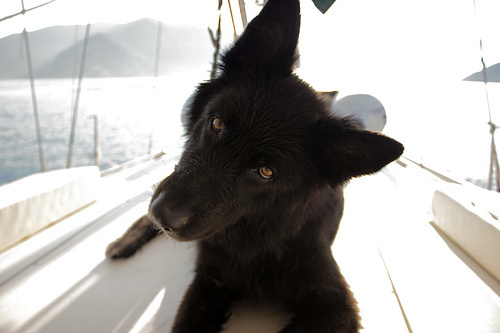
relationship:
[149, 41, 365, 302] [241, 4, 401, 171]
dog black ears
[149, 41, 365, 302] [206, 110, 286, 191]
dog orange eyes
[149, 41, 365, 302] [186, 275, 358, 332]
dog black legs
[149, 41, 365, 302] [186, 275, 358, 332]
dog has black legs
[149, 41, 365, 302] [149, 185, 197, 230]
dog brown nose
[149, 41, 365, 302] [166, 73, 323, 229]
dog big head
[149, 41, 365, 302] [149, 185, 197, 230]
dog cute nose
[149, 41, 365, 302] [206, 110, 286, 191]
dog pretty eyes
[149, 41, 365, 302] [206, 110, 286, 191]
dog dark eyes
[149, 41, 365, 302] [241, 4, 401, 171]
dog big ears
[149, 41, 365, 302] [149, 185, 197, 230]
dog small nose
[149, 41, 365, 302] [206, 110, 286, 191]
dog cute eyes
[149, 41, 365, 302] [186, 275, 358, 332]
dog sticking out legs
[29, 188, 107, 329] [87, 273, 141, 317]
boat has shadow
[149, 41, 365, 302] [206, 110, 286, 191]
dog small eyes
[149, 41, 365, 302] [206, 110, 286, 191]
dog brown eyes